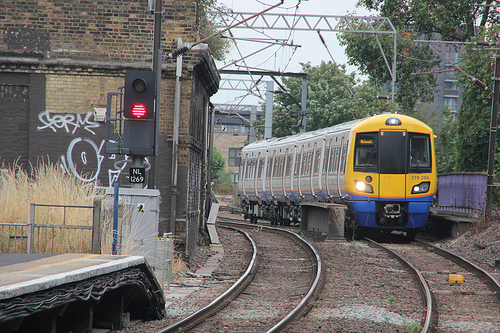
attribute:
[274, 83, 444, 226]
engine — train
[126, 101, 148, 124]
light — glowing, red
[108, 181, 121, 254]
pole — blue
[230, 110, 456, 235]
train — yellow, blue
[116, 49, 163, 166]
traffic light — dimmed 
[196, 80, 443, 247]
train — yellow 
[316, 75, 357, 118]
bush — green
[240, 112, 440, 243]
train — yellow 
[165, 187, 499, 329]
tracks — train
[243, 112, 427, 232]
train — yellow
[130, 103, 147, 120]
light — red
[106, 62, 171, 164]
signal — traffic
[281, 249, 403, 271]
tracks — train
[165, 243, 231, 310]
cement — broken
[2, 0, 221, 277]
building — old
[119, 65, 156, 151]
stoplight — red 